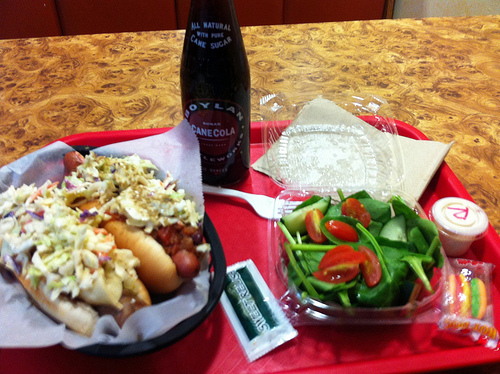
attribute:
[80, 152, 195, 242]
toppings — delicious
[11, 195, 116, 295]
toppings — delicious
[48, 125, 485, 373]
tray — red, plastic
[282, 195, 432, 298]
salad — green, small, red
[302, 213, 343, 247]
tomato — red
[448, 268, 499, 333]
candy — gummy, small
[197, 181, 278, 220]
fork — plastic, white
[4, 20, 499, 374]
table — brown, dinner table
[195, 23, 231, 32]
text — white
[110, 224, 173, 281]
bun — white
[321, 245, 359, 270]
tomato — red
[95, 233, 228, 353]
basket — plastic, black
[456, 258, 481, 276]
bag — plastic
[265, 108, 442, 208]
napkin — paper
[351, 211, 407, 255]
vegetables — gree